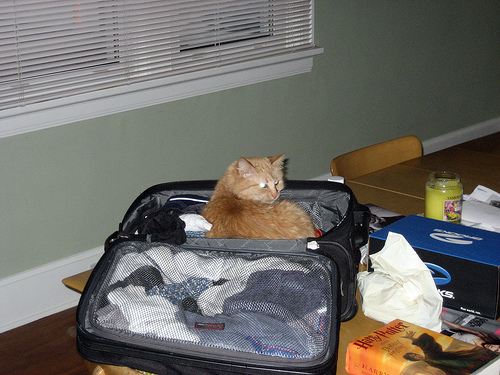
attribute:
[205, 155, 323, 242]
cat — brown, orange, long haired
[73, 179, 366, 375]
case — open, black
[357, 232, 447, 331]
cloth — white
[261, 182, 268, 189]
eye — glowing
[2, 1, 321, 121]
blinds — white, plastic, mini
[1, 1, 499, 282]
wall — gray, green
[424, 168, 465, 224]
candle — scented, yellow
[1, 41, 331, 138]
windowsill — white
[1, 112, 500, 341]
baseboard — white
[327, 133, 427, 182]
chair — wooden, brown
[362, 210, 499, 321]
shoe box — black, blue, white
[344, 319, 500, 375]
book — hardcovered, hardback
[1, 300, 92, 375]
floor — brown, wooden